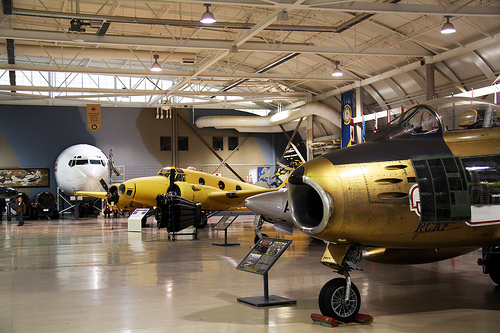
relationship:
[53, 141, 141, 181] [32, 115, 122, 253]
cockpit on airplane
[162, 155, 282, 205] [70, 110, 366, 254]
windows on plane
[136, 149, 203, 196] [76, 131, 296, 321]
cockpit of plane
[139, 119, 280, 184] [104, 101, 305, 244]
windows on wall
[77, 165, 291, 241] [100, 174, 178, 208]
airplane with propellers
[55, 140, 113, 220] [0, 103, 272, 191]
airplane in wall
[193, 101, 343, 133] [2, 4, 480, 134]
tubes in ceiling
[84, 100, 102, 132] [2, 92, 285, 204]
banner on wall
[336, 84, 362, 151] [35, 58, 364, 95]
banner hanging from rafter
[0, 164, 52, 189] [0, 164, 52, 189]
frame in frame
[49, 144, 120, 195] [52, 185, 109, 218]
body on stand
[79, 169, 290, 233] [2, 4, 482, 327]
airplane in building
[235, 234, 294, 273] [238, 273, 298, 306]
sign on base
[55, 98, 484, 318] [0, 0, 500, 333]
airplanes in building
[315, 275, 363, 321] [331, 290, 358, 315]
wheel with rim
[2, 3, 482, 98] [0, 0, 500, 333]
railing in building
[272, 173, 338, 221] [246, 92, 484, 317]
trim on plane